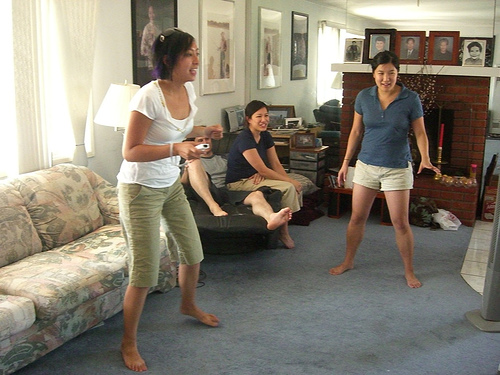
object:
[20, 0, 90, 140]
curtain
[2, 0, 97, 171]
window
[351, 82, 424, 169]
blue shirt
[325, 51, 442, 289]
girl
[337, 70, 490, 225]
fireplace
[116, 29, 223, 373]
girl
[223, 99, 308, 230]
girl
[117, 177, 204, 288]
pants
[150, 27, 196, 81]
dark hair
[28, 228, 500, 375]
carpet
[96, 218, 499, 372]
floor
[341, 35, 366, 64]
picture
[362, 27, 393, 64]
picture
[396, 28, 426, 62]
picture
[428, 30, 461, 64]
picture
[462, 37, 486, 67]
picture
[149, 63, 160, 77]
streak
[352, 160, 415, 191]
shorts